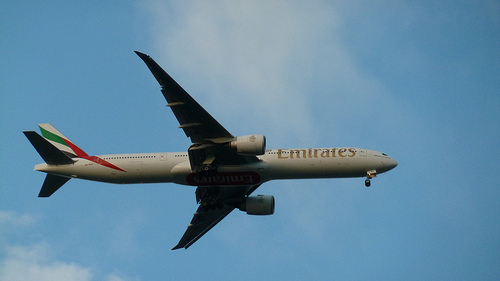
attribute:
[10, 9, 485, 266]
sky — blue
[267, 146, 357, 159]
united emirates — airline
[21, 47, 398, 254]
jet plane — twin engine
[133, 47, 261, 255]
airplane wings — long, providing lift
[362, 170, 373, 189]
airplane gear — retracting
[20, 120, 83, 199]
airplane section — tail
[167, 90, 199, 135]
control surfaces — deployed wing